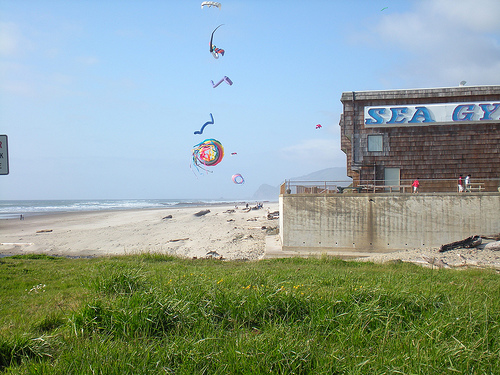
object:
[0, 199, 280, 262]
beach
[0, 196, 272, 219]
ocean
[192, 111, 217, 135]
kites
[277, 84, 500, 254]
shop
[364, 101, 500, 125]
sea gy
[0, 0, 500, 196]
sky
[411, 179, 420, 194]
people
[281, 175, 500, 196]
motel deck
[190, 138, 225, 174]
kite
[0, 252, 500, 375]
grassy strip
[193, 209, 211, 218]
driftwood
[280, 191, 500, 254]
wall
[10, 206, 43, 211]
breaking waves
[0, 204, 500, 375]
land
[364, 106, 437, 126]
word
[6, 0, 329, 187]
air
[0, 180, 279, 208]
distance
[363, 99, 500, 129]
sign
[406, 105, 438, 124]
letter e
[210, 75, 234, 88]
kite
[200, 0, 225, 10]
kite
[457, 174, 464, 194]
person